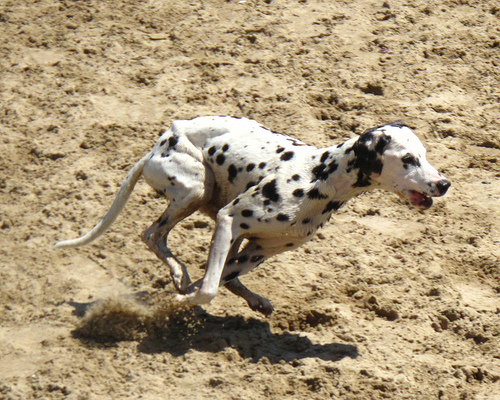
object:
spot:
[278, 150, 293, 160]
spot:
[207, 145, 215, 155]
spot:
[283, 240, 294, 247]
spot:
[158, 138, 169, 148]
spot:
[238, 222, 250, 229]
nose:
[437, 179, 451, 192]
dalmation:
[51, 116, 451, 318]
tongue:
[409, 187, 424, 207]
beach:
[309, 1, 498, 109]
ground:
[0, 0, 498, 399]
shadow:
[70, 298, 356, 360]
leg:
[181, 178, 289, 305]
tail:
[53, 148, 153, 248]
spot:
[400, 150, 424, 170]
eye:
[402, 155, 414, 162]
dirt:
[0, 0, 500, 400]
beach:
[23, 230, 180, 375]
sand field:
[2, 251, 497, 400]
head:
[357, 122, 450, 211]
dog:
[54, 114, 452, 317]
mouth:
[405, 184, 443, 212]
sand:
[0, 0, 498, 400]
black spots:
[252, 177, 301, 208]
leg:
[138, 154, 214, 271]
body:
[136, 117, 322, 318]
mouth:
[404, 183, 440, 208]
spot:
[393, 148, 418, 171]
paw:
[169, 293, 186, 309]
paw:
[171, 277, 193, 292]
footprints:
[0, 0, 500, 400]